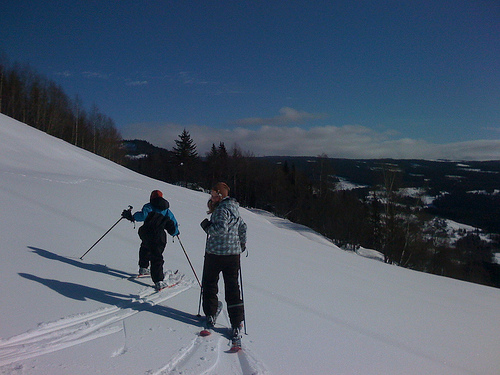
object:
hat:
[211, 182, 231, 198]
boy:
[121, 187, 182, 290]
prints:
[151, 339, 260, 374]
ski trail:
[77, 209, 204, 309]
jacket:
[133, 202, 179, 246]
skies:
[247, 0, 495, 159]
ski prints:
[18, 277, 229, 374]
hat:
[150, 189, 163, 199]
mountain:
[0, 111, 498, 372]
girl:
[200, 180, 248, 339]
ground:
[0, 0, 499, 375]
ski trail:
[7, 267, 226, 374]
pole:
[237, 251, 250, 336]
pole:
[194, 226, 211, 321]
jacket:
[201, 196, 248, 257]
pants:
[138, 226, 169, 284]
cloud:
[236, 103, 338, 128]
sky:
[2, 1, 180, 166]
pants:
[194, 257, 247, 329]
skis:
[225, 328, 243, 353]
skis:
[151, 280, 171, 290]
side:
[177, 200, 202, 313]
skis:
[200, 300, 224, 336]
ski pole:
[176, 233, 205, 288]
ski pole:
[76, 204, 134, 259]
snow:
[0, 103, 484, 373]